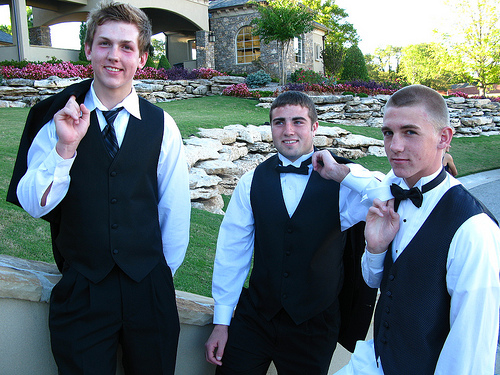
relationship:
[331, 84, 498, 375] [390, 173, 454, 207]
boy wearing tie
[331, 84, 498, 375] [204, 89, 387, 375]
boy with boy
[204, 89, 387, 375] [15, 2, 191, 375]
boy with boy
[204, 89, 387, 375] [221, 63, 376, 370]
boy wearing vest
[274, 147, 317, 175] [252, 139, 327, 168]
bow tie around a neck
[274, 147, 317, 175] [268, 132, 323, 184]
bow tie wrapped around a neck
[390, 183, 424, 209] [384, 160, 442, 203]
bow wrapped around a neck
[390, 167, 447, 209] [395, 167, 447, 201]
bow tie wrapped around a neck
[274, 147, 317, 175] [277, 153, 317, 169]
bow tie wrapped around a neck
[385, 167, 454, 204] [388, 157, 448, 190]
bow tie wrapped around a neck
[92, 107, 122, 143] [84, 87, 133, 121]
tie on neck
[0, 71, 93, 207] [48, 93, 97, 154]
black jacket in hand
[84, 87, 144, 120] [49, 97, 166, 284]
collar folded onto vest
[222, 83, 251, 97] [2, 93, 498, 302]
flower on grass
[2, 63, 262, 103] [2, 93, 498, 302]
flowers on grass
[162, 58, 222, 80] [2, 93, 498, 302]
flowers on grass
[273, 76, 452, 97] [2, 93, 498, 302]
flowers on grass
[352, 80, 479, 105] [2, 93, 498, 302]
flowers on grass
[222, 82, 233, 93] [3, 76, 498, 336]
flower on grass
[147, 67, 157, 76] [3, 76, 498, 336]
flower on grass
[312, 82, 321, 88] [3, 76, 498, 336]
flower on grass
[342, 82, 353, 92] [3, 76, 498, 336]
flower on grass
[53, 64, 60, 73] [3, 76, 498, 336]
flower on grass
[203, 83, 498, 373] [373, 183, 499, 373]
boys wearing vest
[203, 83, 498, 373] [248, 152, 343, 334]
boys wearing vest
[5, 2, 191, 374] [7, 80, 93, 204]
boy carrying jacket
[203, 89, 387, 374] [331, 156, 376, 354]
boy carrying jacket